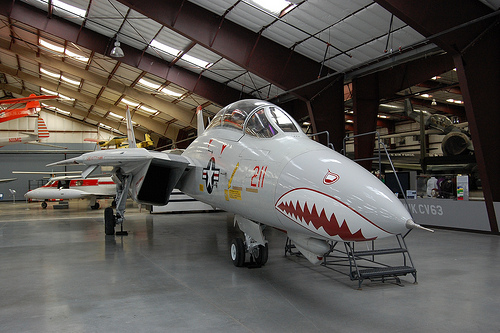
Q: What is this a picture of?
A: A plane.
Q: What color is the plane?
A: Grey.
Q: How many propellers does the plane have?
A: Zero.